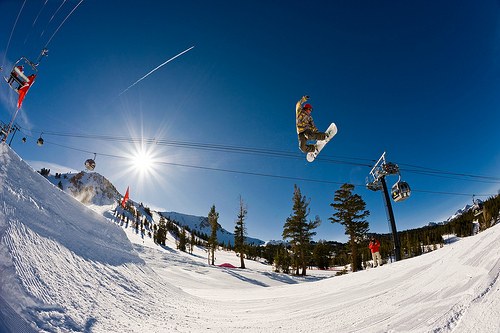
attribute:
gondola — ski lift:
[387, 165, 414, 203]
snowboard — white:
[295, 123, 357, 167]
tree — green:
[281, 182, 321, 275]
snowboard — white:
[315, 118, 337, 143]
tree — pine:
[279, 180, 322, 278]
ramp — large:
[9, 143, 231, 330]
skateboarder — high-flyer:
[289, 90, 339, 165]